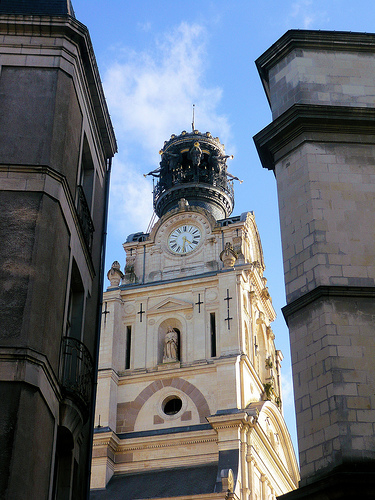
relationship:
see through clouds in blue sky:
[136, 95, 155, 122] [123, 37, 210, 73]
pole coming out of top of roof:
[174, 101, 205, 135] [174, 131, 227, 142]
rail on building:
[54, 334, 99, 419] [3, 2, 119, 499]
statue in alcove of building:
[161, 325, 178, 365] [90, 102, 299, 498]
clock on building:
[165, 222, 201, 255] [90, 102, 299, 498]